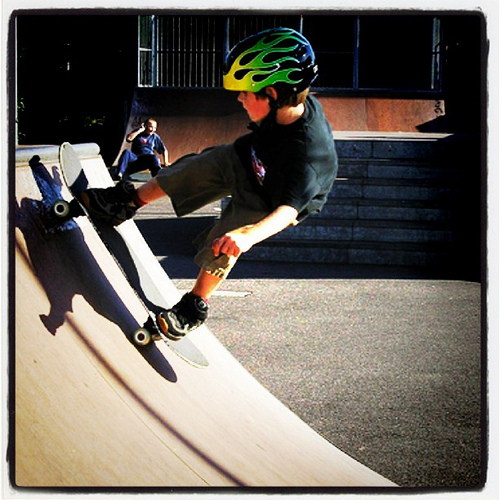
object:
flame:
[222, 28, 320, 94]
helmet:
[217, 30, 320, 93]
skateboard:
[53, 141, 209, 370]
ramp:
[10, 138, 402, 486]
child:
[86, 27, 342, 340]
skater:
[110, 118, 172, 182]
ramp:
[194, 134, 485, 267]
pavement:
[120, 190, 497, 486]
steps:
[194, 133, 486, 272]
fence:
[135, 10, 451, 92]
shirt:
[227, 95, 339, 223]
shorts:
[151, 135, 273, 284]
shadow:
[11, 151, 180, 389]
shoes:
[158, 288, 211, 345]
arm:
[224, 202, 301, 249]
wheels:
[131, 324, 151, 348]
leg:
[116, 143, 234, 215]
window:
[354, 12, 432, 96]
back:
[297, 90, 341, 213]